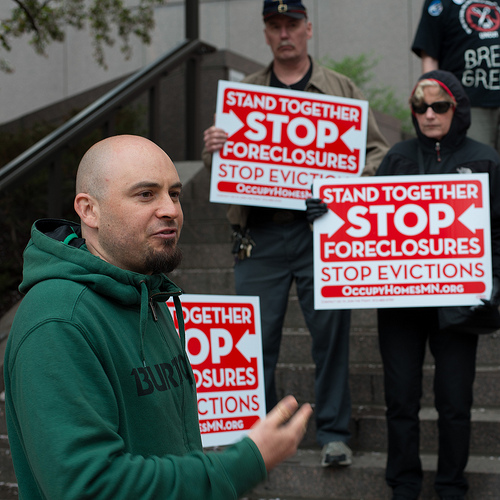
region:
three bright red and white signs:
[161, 77, 495, 434]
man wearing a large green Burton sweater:
[5, 215, 275, 499]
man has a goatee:
[140, 233, 184, 282]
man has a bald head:
[70, 127, 185, 227]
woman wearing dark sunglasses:
[405, 90, 455, 118]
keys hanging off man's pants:
[225, 227, 257, 259]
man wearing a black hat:
[256, 0, 306, 25]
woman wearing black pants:
[368, 303, 480, 494]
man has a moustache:
[271, 32, 294, 52]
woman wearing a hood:
[409, 71, 474, 150]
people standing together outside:
[97, 73, 476, 396]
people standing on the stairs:
[169, 88, 489, 495]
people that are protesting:
[114, 59, 486, 429]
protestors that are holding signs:
[165, 71, 497, 392]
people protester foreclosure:
[171, 79, 493, 424]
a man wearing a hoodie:
[72, 139, 278, 492]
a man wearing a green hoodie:
[83, 171, 306, 496]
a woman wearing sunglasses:
[372, 57, 494, 252]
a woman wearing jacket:
[334, 57, 499, 387]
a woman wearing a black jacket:
[361, 65, 497, 452]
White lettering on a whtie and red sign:
[322, 182, 342, 209]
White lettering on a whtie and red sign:
[336, 186, 389, 200]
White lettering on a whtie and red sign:
[378, 182, 422, 203]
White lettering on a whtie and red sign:
[411, 176, 473, 206]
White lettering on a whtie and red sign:
[331, 203, 443, 233]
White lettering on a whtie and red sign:
[323, 239, 478, 258]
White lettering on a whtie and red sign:
[321, 265, 472, 275]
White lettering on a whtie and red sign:
[226, 89, 366, 121]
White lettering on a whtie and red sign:
[242, 115, 335, 147]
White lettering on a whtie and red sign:
[226, 141, 365, 175]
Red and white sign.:
[314, 168, 491, 312]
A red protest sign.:
[208, 78, 371, 210]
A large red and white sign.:
[162, 290, 268, 449]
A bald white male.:
[0, 133, 315, 499]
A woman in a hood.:
[372, 67, 499, 499]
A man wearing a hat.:
[236, 0, 388, 180]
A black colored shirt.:
[411, 0, 499, 109]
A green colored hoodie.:
[1, 215, 268, 498]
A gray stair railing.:
[0, 31, 222, 187]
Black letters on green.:
[131, 350, 192, 402]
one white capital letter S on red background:
[343, 203, 371, 240]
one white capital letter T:
[369, 202, 396, 239]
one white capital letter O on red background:
[393, 202, 428, 237]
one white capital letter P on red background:
[427, 202, 455, 237]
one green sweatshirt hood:
[9, 219, 79, 290]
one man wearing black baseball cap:
[257, 3, 319, 66]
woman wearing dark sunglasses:
[409, 77, 456, 141]